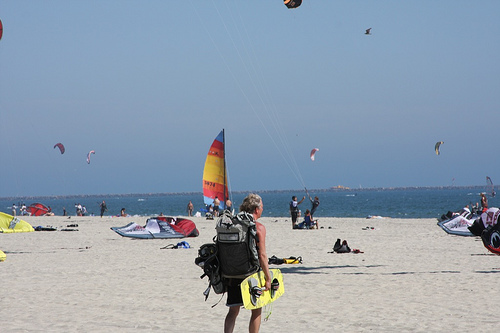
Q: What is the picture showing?
A: It is showing a beach.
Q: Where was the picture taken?
A: It was taken at the beach.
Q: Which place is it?
A: It is a beach.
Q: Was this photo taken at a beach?
A: Yes, it was taken in a beach.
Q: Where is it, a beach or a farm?
A: It is a beach.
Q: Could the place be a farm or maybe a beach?
A: It is a beach.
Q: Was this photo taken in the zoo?
A: No, the picture was taken in the beach.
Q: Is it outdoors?
A: Yes, it is outdoors.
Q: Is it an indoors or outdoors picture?
A: It is outdoors.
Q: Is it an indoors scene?
A: No, it is outdoors.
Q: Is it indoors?
A: No, it is outdoors.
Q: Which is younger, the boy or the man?
A: The boy is younger than the man.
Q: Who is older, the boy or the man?
A: The man is older than the boy.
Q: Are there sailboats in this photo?
A: Yes, there is a sailboat.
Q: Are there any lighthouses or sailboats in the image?
A: Yes, there is a sailboat.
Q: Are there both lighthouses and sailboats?
A: No, there is a sailboat but no lighthouses.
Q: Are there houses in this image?
A: No, there are no houses.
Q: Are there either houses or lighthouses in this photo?
A: No, there are no houses or lighthouses.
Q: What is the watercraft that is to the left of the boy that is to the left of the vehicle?
A: The watercraft is a sailboat.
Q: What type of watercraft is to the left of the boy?
A: The watercraft is a sailboat.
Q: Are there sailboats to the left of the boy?
A: Yes, there is a sailboat to the left of the boy.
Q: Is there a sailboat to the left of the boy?
A: Yes, there is a sailboat to the left of the boy.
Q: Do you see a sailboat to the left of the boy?
A: Yes, there is a sailboat to the left of the boy.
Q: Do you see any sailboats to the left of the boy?
A: Yes, there is a sailboat to the left of the boy.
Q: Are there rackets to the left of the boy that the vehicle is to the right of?
A: No, there is a sailboat to the left of the boy.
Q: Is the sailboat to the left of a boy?
A: Yes, the sailboat is to the left of a boy.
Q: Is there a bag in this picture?
A: Yes, there is a bag.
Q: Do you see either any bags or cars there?
A: Yes, there is a bag.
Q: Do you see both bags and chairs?
A: Yes, there are both a bag and a chair.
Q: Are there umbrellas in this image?
A: No, there are no umbrellas.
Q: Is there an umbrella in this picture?
A: No, there are no umbrellas.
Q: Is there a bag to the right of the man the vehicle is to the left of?
A: Yes, there is a bag to the right of the man.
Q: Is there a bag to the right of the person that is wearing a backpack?
A: Yes, there is a bag to the right of the man.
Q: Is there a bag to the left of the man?
A: No, the bag is to the right of the man.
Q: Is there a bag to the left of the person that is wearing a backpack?
A: No, the bag is to the right of the man.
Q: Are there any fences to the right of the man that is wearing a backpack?
A: No, there is a bag to the right of the man.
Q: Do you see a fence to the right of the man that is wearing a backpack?
A: No, there is a bag to the right of the man.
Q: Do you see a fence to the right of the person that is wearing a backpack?
A: No, there is a bag to the right of the man.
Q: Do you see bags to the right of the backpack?
A: Yes, there is a bag to the right of the backpack.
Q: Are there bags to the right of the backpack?
A: Yes, there is a bag to the right of the backpack.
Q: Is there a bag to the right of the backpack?
A: Yes, there is a bag to the right of the backpack.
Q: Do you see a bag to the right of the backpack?
A: Yes, there is a bag to the right of the backpack.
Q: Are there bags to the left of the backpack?
A: No, the bag is to the right of the backpack.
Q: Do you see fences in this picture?
A: No, there are no fences.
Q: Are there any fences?
A: No, there are no fences.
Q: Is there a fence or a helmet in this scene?
A: No, there are no fences or helmets.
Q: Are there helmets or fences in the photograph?
A: No, there are no fences or helmets.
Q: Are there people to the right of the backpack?
A: Yes, there is a person to the right of the backpack.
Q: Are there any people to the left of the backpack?
A: No, the person is to the right of the backpack.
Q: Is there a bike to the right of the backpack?
A: No, there is a person to the right of the backpack.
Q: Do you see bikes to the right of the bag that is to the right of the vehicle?
A: No, there is a person to the right of the backpack.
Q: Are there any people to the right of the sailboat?
A: Yes, there is a person to the right of the sailboat.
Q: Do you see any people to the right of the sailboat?
A: Yes, there is a person to the right of the sailboat.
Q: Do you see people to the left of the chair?
A: Yes, there is a person to the left of the chair.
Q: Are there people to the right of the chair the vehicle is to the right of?
A: No, the person is to the left of the chair.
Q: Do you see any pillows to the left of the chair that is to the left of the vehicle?
A: No, there is a person to the left of the chair.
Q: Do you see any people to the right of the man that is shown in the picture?
A: Yes, there is a person to the right of the man.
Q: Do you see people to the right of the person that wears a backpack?
A: Yes, there is a person to the right of the man.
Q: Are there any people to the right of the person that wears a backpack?
A: Yes, there is a person to the right of the man.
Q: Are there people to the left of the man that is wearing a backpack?
A: No, the person is to the right of the man.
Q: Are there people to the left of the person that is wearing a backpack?
A: No, the person is to the right of the man.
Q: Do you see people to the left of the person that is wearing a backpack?
A: No, the person is to the right of the man.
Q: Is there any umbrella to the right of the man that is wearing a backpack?
A: No, there is a person to the right of the man.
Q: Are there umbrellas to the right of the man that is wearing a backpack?
A: No, there is a person to the right of the man.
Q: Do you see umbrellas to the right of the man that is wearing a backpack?
A: No, there is a person to the right of the man.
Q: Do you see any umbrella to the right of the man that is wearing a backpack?
A: No, there is a person to the right of the man.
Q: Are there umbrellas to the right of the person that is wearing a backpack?
A: No, there is a person to the right of the man.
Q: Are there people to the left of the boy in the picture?
A: Yes, there is a person to the left of the boy.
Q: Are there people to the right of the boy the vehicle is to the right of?
A: No, the person is to the left of the boy.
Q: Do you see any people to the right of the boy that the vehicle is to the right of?
A: No, the person is to the left of the boy.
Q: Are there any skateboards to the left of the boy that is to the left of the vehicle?
A: No, there is a person to the left of the boy.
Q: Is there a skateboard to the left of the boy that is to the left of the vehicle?
A: No, there is a person to the left of the boy.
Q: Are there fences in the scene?
A: No, there are no fences.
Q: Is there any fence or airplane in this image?
A: No, there are no fences or airplanes.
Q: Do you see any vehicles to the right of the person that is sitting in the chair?
A: Yes, there is a vehicle to the right of the person.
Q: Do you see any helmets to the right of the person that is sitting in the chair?
A: No, there is a vehicle to the right of the person.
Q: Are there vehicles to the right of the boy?
A: Yes, there is a vehicle to the right of the boy.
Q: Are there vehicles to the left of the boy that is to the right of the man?
A: No, the vehicle is to the right of the boy.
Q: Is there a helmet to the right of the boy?
A: No, there is a vehicle to the right of the boy.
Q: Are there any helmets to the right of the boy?
A: No, there is a vehicle to the right of the boy.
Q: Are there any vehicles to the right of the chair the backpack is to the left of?
A: Yes, there is a vehicle to the right of the chair.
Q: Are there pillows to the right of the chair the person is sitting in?
A: No, there is a vehicle to the right of the chair.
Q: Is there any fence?
A: No, there are no fences.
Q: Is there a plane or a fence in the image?
A: No, there are no fences or airplanes.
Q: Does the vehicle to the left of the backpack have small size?
A: Yes, the vehicle is small.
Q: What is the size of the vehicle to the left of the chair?
A: The vehicle is small.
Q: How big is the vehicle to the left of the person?
A: The vehicle is small.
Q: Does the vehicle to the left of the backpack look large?
A: No, the vehicle is small.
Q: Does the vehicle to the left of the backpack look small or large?
A: The vehicle is small.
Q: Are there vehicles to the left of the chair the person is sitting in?
A: Yes, there is a vehicle to the left of the chair.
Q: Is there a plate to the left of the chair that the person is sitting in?
A: No, there is a vehicle to the left of the chair.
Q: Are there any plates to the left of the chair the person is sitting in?
A: No, there is a vehicle to the left of the chair.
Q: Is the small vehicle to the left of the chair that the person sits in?
A: Yes, the vehicle is to the left of the chair.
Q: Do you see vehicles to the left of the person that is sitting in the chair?
A: Yes, there is a vehicle to the left of the person.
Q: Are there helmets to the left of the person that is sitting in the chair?
A: No, there is a vehicle to the left of the person.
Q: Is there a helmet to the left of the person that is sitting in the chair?
A: No, there is a vehicle to the left of the person.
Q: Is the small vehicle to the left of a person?
A: Yes, the vehicle is to the left of a person.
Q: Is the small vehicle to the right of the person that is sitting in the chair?
A: No, the vehicle is to the left of the person.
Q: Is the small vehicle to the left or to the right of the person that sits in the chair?
A: The vehicle is to the left of the person.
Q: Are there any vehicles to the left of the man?
A: Yes, there is a vehicle to the left of the man.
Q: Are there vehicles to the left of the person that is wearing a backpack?
A: Yes, there is a vehicle to the left of the man.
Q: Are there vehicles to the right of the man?
A: No, the vehicle is to the left of the man.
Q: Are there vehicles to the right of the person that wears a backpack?
A: No, the vehicle is to the left of the man.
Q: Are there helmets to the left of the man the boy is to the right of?
A: No, there is a vehicle to the left of the man.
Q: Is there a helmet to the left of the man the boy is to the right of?
A: No, there is a vehicle to the left of the man.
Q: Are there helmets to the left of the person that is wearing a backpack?
A: No, there is a vehicle to the left of the man.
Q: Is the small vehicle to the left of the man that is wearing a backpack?
A: Yes, the vehicle is to the left of the man.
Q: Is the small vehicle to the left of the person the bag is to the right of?
A: Yes, the vehicle is to the left of the man.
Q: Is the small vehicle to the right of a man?
A: No, the vehicle is to the left of a man.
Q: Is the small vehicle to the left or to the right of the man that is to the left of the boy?
A: The vehicle is to the left of the man.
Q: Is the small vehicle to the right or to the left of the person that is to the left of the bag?
A: The vehicle is to the left of the man.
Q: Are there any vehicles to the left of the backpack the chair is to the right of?
A: Yes, there is a vehicle to the left of the backpack.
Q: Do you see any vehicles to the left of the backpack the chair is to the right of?
A: Yes, there is a vehicle to the left of the backpack.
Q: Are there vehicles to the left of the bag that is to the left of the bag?
A: Yes, there is a vehicle to the left of the backpack.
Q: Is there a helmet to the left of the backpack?
A: No, there is a vehicle to the left of the backpack.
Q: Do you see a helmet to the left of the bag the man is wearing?
A: No, there is a vehicle to the left of the backpack.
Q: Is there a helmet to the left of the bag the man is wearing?
A: No, there is a vehicle to the left of the backpack.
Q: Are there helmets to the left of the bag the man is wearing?
A: No, there is a vehicle to the left of the backpack.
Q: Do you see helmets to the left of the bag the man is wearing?
A: No, there is a vehicle to the left of the backpack.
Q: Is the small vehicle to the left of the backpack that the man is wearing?
A: Yes, the vehicle is to the left of the backpack.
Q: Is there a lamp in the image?
A: No, there are no lamps.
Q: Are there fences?
A: No, there are no fences.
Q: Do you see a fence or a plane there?
A: No, there are no fences or airplanes.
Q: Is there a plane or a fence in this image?
A: No, there are no fences or airplanes.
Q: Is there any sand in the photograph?
A: Yes, there is sand.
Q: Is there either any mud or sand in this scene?
A: Yes, there is sand.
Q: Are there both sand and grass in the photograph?
A: No, there is sand but no grass.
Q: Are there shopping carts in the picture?
A: No, there are no shopping carts.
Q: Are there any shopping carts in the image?
A: No, there are no shopping carts.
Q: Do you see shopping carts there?
A: No, there are no shopping carts.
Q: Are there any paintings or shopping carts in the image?
A: No, there are no shopping carts or paintings.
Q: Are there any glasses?
A: No, there are no glasses.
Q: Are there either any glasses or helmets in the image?
A: No, there are no glasses or helmets.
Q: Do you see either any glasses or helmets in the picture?
A: No, there are no glasses or helmets.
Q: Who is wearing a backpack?
A: The man is wearing a backpack.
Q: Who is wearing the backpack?
A: The man is wearing a backpack.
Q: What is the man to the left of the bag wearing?
A: The man is wearing a backpack.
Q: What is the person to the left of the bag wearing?
A: The man is wearing a backpack.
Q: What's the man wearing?
A: The man is wearing a backpack.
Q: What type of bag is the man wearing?
A: The man is wearing a backpack.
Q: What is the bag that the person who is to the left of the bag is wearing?
A: The bag is a backpack.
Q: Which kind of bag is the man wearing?
A: The man is wearing a backpack.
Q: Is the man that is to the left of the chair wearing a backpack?
A: Yes, the man is wearing a backpack.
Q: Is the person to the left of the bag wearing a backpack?
A: Yes, the man is wearing a backpack.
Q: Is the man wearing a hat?
A: No, the man is wearing a backpack.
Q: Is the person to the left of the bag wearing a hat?
A: No, the man is wearing a backpack.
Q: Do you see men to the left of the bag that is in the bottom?
A: Yes, there is a man to the left of the bag.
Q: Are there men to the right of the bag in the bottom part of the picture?
A: No, the man is to the left of the bag.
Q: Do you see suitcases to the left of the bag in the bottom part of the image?
A: No, there is a man to the left of the bag.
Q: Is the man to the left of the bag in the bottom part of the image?
A: Yes, the man is to the left of the bag.